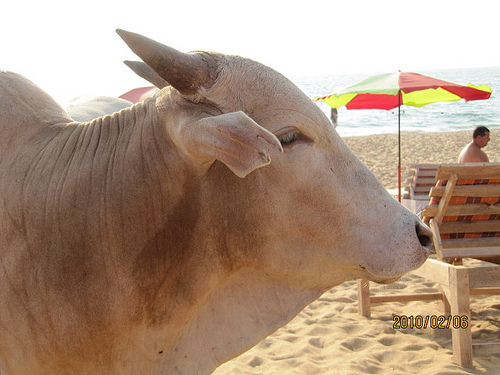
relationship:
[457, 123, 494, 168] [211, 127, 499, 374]
man sitting on beach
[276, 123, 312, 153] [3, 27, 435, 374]
eye of cow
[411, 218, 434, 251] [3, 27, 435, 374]
nostril of cow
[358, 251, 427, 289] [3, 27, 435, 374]
mouth of cow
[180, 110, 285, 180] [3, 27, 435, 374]
ear of cow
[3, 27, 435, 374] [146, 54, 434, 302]
cow has head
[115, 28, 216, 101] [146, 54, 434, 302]
horn on head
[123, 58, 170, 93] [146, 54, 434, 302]
horn on head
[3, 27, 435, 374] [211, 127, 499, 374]
cow on beach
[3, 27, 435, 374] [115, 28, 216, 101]
cow has horn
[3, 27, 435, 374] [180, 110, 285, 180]
cow has ear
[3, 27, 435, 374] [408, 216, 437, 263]
cow has nose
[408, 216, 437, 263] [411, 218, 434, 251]
nose has nostril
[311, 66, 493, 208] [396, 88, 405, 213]
umbrella has pole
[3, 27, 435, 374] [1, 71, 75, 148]
cow has hump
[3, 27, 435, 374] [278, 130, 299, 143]
cow has eyelashes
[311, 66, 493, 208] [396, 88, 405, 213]
umbrella on pole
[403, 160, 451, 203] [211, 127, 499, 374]
beach chair on beach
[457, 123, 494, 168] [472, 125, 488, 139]
man has hair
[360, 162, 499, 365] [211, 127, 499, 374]
chair on beach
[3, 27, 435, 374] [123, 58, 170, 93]
cow has horn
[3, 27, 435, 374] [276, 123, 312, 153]
cow has eye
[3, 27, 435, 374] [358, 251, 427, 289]
cow has mouth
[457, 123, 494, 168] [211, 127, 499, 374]
man on beach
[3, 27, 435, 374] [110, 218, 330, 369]
cow has neck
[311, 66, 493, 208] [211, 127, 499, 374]
umbrella on beach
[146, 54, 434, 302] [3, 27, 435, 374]
head of cow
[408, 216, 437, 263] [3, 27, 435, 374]
nose of cow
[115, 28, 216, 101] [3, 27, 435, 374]
horn of cow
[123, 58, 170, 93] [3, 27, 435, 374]
horn of cow